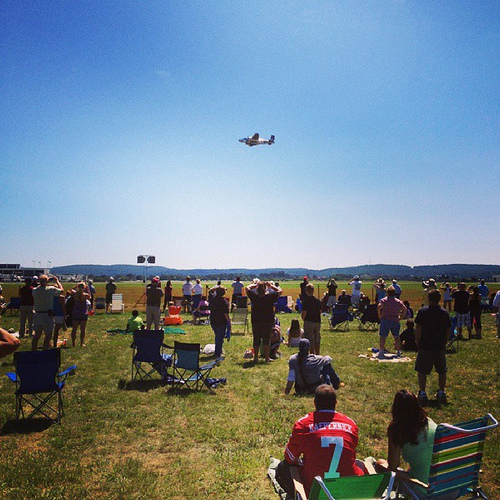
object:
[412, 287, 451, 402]
person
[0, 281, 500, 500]
field area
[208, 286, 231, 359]
person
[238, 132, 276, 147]
plane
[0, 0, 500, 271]
sky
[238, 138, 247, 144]
nose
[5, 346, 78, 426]
chair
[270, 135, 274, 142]
tail